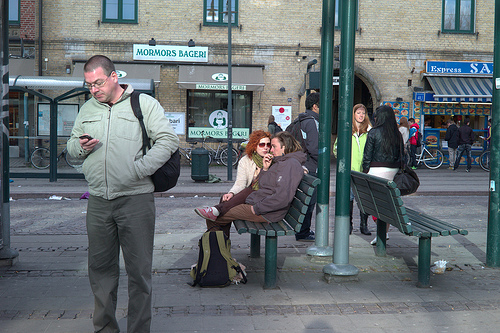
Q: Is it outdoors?
A: Yes, it is outdoors.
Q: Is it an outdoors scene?
A: Yes, it is outdoors.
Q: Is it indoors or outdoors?
A: It is outdoors.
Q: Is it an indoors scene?
A: No, it is outdoors.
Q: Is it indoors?
A: No, it is outdoors.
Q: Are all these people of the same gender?
A: No, they are both male and female.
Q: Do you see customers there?
A: No, there are no customers.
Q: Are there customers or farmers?
A: No, there are no customers or farmers.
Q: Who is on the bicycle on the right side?
A: The man is on the bicycle.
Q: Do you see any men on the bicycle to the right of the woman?
A: Yes, there is a man on the bicycle.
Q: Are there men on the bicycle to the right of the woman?
A: Yes, there is a man on the bicycle.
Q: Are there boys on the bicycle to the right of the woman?
A: No, there is a man on the bicycle.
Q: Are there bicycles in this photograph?
A: Yes, there is a bicycle.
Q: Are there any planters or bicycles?
A: Yes, there is a bicycle.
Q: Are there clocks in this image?
A: No, there are no clocks.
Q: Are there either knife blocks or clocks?
A: No, there are no clocks or knife blocks.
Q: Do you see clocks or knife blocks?
A: No, there are no clocks or knife blocks.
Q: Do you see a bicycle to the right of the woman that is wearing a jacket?
A: Yes, there is a bicycle to the right of the woman.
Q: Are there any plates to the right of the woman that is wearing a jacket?
A: No, there is a bicycle to the right of the woman.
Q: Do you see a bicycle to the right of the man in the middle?
A: Yes, there is a bicycle to the right of the man.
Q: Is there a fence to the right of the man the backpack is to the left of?
A: No, there is a bicycle to the right of the man.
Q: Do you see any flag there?
A: No, there are no flags.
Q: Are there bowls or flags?
A: No, there are no flags or bowls.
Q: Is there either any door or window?
A: Yes, there are windows.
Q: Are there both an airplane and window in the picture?
A: No, there are windows but no airplanes.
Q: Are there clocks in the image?
A: No, there are no clocks.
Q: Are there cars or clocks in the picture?
A: No, there are no clocks or cars.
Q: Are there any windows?
A: Yes, there is a window.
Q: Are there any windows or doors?
A: Yes, there is a window.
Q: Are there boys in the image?
A: No, there are no boys.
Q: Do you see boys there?
A: No, there are no boys.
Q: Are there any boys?
A: No, there are no boys.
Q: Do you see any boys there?
A: No, there are no boys.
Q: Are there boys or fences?
A: No, there are no boys or fences.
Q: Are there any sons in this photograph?
A: No, there are no sons.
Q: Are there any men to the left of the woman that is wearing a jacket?
A: Yes, there is a man to the left of the woman.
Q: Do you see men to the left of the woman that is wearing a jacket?
A: Yes, there is a man to the left of the woman.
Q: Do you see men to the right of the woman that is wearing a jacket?
A: No, the man is to the left of the woman.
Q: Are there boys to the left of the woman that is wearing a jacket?
A: No, there is a man to the left of the woman.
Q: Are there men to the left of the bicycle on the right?
A: Yes, there is a man to the left of the bicycle.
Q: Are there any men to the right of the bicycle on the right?
A: No, the man is to the left of the bicycle.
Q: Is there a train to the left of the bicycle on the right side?
A: No, there is a man to the left of the bicycle.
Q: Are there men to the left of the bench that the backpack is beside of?
A: Yes, there is a man to the left of the bench.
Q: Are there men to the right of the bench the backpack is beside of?
A: No, the man is to the left of the bench.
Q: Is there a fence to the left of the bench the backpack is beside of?
A: No, there is a man to the left of the bench.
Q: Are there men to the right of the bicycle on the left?
A: Yes, there is a man to the right of the bicycle.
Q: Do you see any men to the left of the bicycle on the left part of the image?
A: No, the man is to the right of the bicycle.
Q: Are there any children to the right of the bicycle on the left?
A: No, there is a man to the right of the bicycle.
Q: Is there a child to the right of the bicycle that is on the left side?
A: No, there is a man to the right of the bicycle.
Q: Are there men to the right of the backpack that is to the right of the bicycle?
A: Yes, there is a man to the right of the backpack.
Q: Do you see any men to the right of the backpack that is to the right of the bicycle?
A: Yes, there is a man to the right of the backpack.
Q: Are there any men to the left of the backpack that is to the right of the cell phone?
A: No, the man is to the right of the backpack.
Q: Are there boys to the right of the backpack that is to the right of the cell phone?
A: No, there is a man to the right of the backpack.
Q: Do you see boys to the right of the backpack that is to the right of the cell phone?
A: No, there is a man to the right of the backpack.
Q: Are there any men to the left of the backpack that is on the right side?
A: Yes, there is a man to the left of the backpack.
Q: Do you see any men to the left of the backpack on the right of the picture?
A: Yes, there is a man to the left of the backpack.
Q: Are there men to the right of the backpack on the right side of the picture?
A: No, the man is to the left of the backpack.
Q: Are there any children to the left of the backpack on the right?
A: No, there is a man to the left of the backpack.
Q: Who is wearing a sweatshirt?
A: The man is wearing a sweatshirt.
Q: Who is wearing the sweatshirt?
A: The man is wearing a sweatshirt.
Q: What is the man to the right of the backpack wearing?
A: The man is wearing a sweatshirt.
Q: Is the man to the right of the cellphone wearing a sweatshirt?
A: Yes, the man is wearing a sweatshirt.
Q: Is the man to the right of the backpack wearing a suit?
A: No, the man is wearing a sweatshirt.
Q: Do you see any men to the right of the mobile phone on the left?
A: Yes, there is a man to the right of the cellphone.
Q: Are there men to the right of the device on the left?
A: Yes, there is a man to the right of the cellphone.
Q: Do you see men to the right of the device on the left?
A: Yes, there is a man to the right of the cellphone.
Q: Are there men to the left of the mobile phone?
A: No, the man is to the right of the mobile phone.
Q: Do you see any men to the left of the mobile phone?
A: No, the man is to the right of the mobile phone.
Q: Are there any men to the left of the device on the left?
A: No, the man is to the right of the mobile phone.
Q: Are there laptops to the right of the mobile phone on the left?
A: No, there is a man to the right of the cellphone.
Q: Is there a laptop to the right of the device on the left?
A: No, there is a man to the right of the cellphone.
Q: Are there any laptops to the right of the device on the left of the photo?
A: No, there is a man to the right of the cellphone.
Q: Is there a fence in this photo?
A: No, there are no fences.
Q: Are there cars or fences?
A: No, there are no fences or cars.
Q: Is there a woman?
A: Yes, there is a woman.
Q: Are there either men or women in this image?
A: Yes, there is a woman.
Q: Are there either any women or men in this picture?
A: Yes, there is a woman.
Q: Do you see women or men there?
A: Yes, there is a woman.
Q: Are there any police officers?
A: No, there are no police officers.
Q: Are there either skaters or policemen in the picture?
A: No, there are no policemen or skaters.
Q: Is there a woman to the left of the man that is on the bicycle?
A: Yes, there is a woman to the left of the man.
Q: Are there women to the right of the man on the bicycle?
A: No, the woman is to the left of the man.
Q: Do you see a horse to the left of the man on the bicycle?
A: No, there is a woman to the left of the man.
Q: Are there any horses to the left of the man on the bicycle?
A: No, there is a woman to the left of the man.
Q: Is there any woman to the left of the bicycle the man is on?
A: Yes, there is a woman to the left of the bicycle.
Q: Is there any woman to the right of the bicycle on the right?
A: No, the woman is to the left of the bicycle.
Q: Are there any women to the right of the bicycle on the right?
A: No, the woman is to the left of the bicycle.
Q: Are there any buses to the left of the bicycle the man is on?
A: No, there is a woman to the left of the bicycle.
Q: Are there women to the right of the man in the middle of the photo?
A: Yes, there is a woman to the right of the man.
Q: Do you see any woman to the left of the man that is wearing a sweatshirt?
A: No, the woman is to the right of the man.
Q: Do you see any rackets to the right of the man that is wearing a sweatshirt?
A: No, there is a woman to the right of the man.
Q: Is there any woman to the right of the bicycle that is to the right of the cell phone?
A: Yes, there is a woman to the right of the bicycle.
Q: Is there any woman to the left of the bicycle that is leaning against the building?
A: No, the woman is to the right of the bicycle.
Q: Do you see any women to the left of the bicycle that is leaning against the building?
A: No, the woman is to the right of the bicycle.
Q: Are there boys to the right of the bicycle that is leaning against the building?
A: No, there is a woman to the right of the bicycle.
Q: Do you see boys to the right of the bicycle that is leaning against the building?
A: No, there is a woman to the right of the bicycle.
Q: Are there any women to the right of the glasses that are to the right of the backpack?
A: Yes, there is a woman to the right of the glasses.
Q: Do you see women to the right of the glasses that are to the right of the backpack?
A: Yes, there is a woman to the right of the glasses.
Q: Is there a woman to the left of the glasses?
A: No, the woman is to the right of the glasses.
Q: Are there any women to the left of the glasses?
A: No, the woman is to the right of the glasses.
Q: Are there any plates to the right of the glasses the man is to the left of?
A: No, there is a woman to the right of the glasses.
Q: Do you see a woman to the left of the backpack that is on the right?
A: Yes, there is a woman to the left of the backpack.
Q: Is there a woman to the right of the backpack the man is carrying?
A: No, the woman is to the left of the backpack.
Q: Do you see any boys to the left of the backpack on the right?
A: No, there is a woman to the left of the backpack.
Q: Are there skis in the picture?
A: No, there are no skis.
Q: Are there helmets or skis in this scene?
A: No, there are no skis or helmets.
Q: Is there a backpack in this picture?
A: Yes, there is a backpack.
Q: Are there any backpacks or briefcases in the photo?
A: Yes, there is a backpack.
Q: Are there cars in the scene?
A: No, there are no cars.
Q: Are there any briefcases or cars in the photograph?
A: No, there are no cars or briefcases.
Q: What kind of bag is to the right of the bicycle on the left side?
A: The bag is a backpack.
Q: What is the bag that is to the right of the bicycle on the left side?
A: The bag is a backpack.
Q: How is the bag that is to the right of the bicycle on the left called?
A: The bag is a backpack.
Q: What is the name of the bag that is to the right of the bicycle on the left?
A: The bag is a backpack.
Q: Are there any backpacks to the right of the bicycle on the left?
A: Yes, there is a backpack to the right of the bicycle.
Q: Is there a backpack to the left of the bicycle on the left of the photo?
A: No, the backpack is to the right of the bicycle.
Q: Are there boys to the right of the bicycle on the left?
A: No, there is a backpack to the right of the bicycle.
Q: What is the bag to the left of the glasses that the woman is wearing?
A: The bag is a backpack.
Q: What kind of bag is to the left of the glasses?
A: The bag is a backpack.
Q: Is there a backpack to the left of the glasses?
A: Yes, there is a backpack to the left of the glasses.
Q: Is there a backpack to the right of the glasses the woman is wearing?
A: No, the backpack is to the left of the glasses.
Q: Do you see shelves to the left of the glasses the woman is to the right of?
A: No, there is a backpack to the left of the glasses.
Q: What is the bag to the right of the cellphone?
A: The bag is a backpack.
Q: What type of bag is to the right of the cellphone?
A: The bag is a backpack.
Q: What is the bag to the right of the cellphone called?
A: The bag is a backpack.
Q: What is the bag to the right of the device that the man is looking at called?
A: The bag is a backpack.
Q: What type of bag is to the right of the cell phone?
A: The bag is a backpack.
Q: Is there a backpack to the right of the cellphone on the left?
A: Yes, there is a backpack to the right of the mobile phone.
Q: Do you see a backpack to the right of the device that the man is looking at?
A: Yes, there is a backpack to the right of the mobile phone.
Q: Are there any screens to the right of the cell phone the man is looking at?
A: No, there is a backpack to the right of the cellphone.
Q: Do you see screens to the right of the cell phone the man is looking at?
A: No, there is a backpack to the right of the cellphone.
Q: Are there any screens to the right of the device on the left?
A: No, there is a backpack to the right of the cellphone.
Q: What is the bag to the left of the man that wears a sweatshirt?
A: The bag is a backpack.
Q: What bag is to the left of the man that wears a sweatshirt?
A: The bag is a backpack.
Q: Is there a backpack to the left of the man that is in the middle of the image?
A: Yes, there is a backpack to the left of the man.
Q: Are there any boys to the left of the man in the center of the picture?
A: No, there is a backpack to the left of the man.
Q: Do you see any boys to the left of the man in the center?
A: No, there is a backpack to the left of the man.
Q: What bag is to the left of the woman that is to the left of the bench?
A: The bag is a backpack.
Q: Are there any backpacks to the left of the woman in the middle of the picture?
A: Yes, there is a backpack to the left of the woman.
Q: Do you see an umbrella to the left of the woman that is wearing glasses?
A: No, there is a backpack to the left of the woman.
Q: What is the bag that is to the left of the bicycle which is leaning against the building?
A: The bag is a backpack.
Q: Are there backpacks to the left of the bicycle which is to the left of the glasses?
A: Yes, there is a backpack to the left of the bicycle.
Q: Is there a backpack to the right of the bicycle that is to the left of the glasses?
A: No, the backpack is to the left of the bicycle.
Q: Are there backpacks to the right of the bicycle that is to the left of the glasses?
A: No, the backpack is to the left of the bicycle.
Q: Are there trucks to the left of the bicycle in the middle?
A: No, there is a backpack to the left of the bicycle.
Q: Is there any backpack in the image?
A: Yes, there is a backpack.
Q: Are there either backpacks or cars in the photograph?
A: Yes, there is a backpack.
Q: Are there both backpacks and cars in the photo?
A: No, there is a backpack but no cars.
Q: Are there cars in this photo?
A: No, there are no cars.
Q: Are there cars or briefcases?
A: No, there are no cars or briefcases.